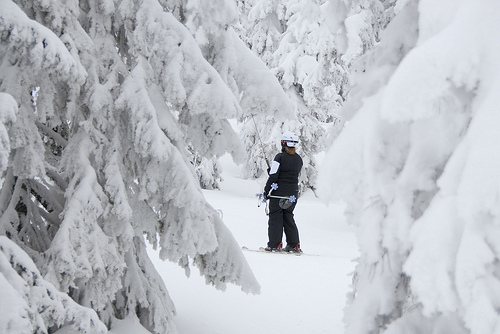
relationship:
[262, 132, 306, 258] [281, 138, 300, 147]
person with goggles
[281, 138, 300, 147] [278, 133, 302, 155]
goggles on head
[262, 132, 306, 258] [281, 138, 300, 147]
guy with goggles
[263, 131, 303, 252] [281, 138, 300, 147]
guy with goggles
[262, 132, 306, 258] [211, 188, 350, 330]
person in snow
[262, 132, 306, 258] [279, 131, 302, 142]
person with hat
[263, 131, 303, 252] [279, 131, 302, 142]
guy with hat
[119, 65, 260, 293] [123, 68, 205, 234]
branch has snow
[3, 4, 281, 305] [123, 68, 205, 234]
trees covered in snow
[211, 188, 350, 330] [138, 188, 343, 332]
snow on ground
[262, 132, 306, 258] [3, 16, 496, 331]
person in forest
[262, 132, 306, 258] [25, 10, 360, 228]
person looking at scenery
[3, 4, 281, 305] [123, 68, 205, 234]
trees have snow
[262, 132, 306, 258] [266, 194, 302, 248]
person wearing pants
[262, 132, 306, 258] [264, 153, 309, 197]
person wearing jacket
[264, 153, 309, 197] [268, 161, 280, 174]
jacket has patches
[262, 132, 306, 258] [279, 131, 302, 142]
person wearing hat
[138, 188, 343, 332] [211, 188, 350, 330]
ground has snow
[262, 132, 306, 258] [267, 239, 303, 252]
person wearing boots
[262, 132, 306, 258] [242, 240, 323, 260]
person has skiis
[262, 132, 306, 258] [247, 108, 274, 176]
person carrying pole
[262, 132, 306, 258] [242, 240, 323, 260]
person on skiis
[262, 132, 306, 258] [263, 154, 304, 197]
person wearing coat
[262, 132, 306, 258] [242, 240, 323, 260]
person standing on skiis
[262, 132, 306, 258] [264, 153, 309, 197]
person in jacket